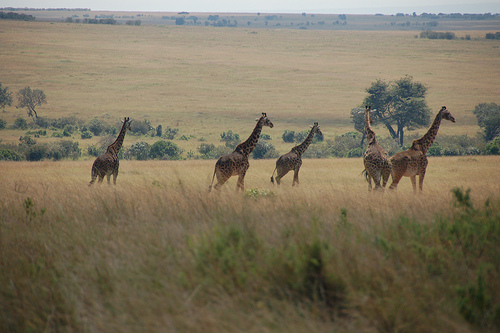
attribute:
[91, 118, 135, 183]
giraffe — tall, wandering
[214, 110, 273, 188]
giraffe — tall, wandering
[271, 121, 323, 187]
giraffe — tall, wandering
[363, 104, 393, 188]
giraffe — tall, wandering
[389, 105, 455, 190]
giraffe — tall, wandering